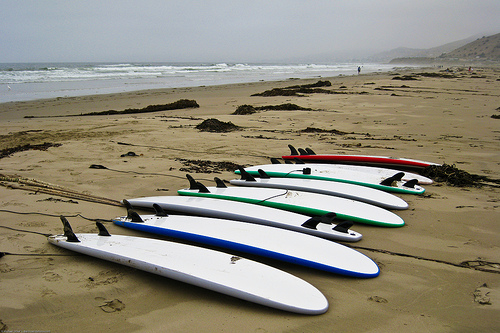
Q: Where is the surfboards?
A: On beach.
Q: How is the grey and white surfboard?
A: Laying down.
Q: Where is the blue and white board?
A: On sand.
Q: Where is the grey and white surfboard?
A: On the end.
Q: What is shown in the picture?
A: A beach.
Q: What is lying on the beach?
A: Surf boards.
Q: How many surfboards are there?
A: Eight.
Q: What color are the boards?
A: White.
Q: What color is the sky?
A: Grey.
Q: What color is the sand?
A: Beige.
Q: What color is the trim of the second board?
A: Blue.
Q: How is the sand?
A: Packed.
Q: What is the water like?
A: Wavy.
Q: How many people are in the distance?
A: Two.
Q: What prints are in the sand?
A: Footprints.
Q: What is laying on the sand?
A: Surfboards.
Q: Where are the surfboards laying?
A: Sand.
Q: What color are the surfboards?
A: White.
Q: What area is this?
A: Beach.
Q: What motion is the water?
A: Wavy.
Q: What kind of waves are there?
A: Choppy.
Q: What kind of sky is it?
A: Overcast.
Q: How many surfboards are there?
A: 8.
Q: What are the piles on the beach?
A: Seaweed.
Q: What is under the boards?
A: Sand.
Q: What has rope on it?
A: Surfboards.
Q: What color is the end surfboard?
A: Red.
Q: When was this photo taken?
A: The daytime.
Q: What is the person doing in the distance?
A: Walking.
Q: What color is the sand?
A: Tan.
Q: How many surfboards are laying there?
A: 7.